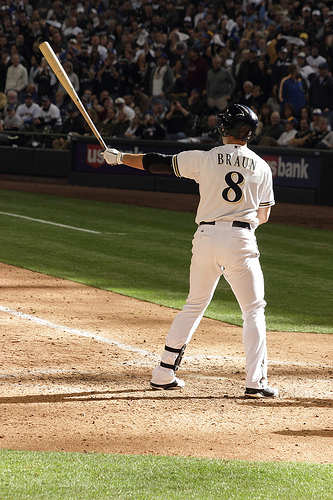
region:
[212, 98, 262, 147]
the head of a man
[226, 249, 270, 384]
the leg of a man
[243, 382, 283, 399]
a black and white shoe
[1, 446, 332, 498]
a patch of green grass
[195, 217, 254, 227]
a black leather belt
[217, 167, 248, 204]
a number on the uniform top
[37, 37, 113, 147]
a brown baseball bat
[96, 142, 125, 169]
a white batting glove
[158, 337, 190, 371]
a black shin guard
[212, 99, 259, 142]
a black batting helmet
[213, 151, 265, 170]
The name BRAUN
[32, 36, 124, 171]
A baseball bat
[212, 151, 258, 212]
A baseball player BRAUN number 8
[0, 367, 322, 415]
A person's shadow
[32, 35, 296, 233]
A baseball player holding a bat aloft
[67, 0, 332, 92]
A crowd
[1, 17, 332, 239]
The crowd at a baseball game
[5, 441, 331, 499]
Grass meeting a patch of dirt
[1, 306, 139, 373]
A white chalk line through dirt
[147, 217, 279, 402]
A man wearing white pants, and pads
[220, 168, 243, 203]
the number eight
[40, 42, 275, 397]
a baseball player with a bat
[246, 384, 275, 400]
a baseball player's right foot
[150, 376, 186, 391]
a baseball player's left shoe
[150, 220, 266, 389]
a baseball player's pants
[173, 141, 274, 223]
a baseball player's shirt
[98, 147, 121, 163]
a man's left glove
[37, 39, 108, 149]
a wooden baseball bat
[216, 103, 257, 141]
a baseball player's helmet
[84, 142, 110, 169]
part of the logo for US Bank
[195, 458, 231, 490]
part of some grass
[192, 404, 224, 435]
part of a ground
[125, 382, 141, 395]
part of a shade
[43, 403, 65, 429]
part of a ground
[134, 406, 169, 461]
part of a ground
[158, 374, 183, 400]
edge of a shoe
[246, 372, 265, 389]
edge of a trouser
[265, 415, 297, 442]
edge of a shade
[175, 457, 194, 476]
part of some grass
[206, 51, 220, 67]
part of a head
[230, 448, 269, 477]
edge of a field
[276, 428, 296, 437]
part of a shade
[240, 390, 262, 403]
edge of a shoe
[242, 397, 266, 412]
edge of a shoe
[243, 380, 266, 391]
edge of a trouser